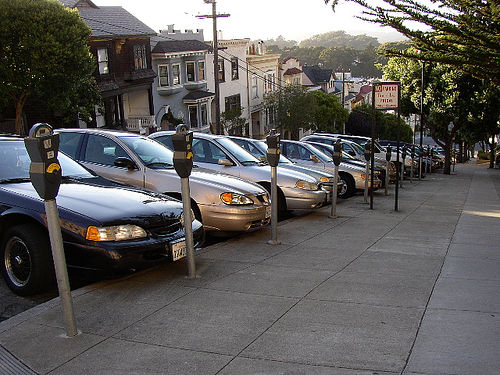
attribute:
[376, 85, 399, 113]
sign — red and white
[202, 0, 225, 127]
pole — tall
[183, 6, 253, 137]
pole — light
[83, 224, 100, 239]
turn signal — yellow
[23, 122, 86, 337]
meter — far-left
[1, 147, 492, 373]
sidewalk — cemented, clean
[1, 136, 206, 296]
car — black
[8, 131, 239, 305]
car — registration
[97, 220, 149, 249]
headlight — white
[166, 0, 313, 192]
pole — electricity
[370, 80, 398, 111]
sign — no parking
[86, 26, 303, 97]
wire — thick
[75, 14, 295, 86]
wire — thick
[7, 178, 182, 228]
hood — shiny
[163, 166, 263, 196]
hood — shiny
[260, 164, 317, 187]
hood — shiny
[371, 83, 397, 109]
sign — square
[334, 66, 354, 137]
pole — tall, wooden, utility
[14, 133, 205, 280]
car — black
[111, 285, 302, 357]
square — concrete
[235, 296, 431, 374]
square — sidewalk